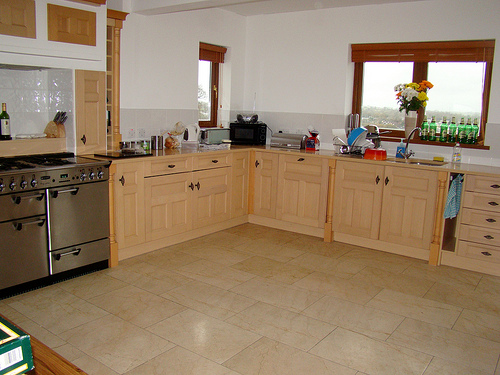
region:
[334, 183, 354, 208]
part of a board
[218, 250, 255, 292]
part of a floor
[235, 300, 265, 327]
part of a lined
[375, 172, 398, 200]
part of a handke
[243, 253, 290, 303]
part of a floor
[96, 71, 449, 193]
the view is in a kitchen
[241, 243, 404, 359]
the floor is covered by brown tiles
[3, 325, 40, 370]
the box is green in color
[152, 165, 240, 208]
the drawers are light brown in color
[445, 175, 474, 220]
the towel is blue in color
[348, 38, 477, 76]
th window frames are brwon in color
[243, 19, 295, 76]
the walls are white in color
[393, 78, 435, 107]
the flowers are yellow and white in color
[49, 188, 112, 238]
the cooker is silvery in color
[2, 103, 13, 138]
the wine bottle is green in color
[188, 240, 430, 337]
the floor is clean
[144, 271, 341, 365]
the floor is clean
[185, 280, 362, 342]
the floor is clean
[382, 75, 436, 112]
the flowers are colorful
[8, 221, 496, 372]
Tan ceramic floor tile.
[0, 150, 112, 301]
A stainless steel oven.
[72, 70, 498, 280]
Brown wooden kitchen cupboards.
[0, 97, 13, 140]
A dark bottle with a white label behind the stove.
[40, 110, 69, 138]
Knives in a wooden block behind the stove.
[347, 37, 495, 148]
A brown framed window above the sink.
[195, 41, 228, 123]
A brown framed window above the countertop.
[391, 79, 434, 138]
Flowers in a tan vase sitting on the window sill.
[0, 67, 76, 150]
White tiles on the wall behind the stove.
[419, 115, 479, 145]
Green liquid in seven bottles on the window sill.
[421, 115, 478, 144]
the green bottles on the window sill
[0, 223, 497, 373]
the tiles on the kitchen floor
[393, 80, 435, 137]
the flowers in the window sill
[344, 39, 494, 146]
the larger window in the kitchen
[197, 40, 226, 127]
the smaller window in the kitchen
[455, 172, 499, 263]
the five drawers under the counter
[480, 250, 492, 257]
the handle on the drawer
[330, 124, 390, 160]
the dishes next to the sink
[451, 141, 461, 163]
the plastic bottle for the dish soap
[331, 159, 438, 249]
the doors under the sink